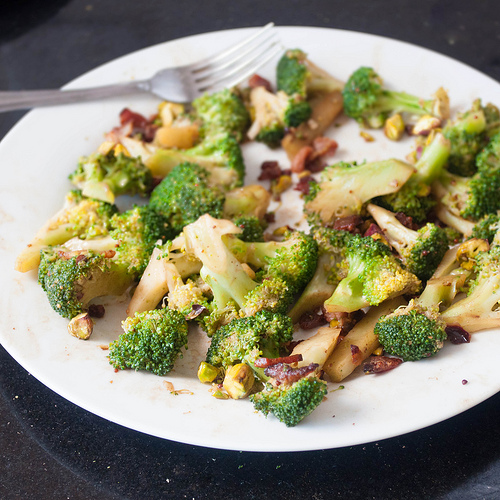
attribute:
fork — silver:
[2, 21, 286, 103]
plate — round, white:
[2, 25, 500, 454]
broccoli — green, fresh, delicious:
[15, 48, 496, 426]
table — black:
[4, 2, 496, 499]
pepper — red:
[60, 73, 473, 385]